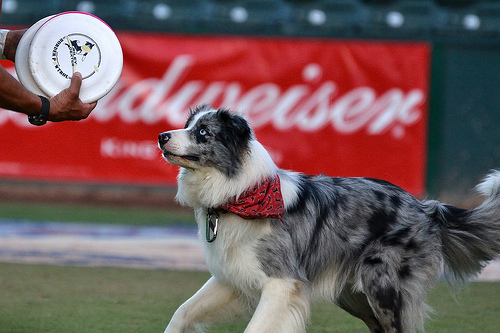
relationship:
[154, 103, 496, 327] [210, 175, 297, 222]
dog with scarf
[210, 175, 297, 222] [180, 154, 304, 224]
scarf around neck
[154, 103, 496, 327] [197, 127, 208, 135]
dog with eye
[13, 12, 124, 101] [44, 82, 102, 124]
frisbie in hand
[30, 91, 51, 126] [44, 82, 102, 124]
watch on hand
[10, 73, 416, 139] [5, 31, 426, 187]
budweiser on front of sign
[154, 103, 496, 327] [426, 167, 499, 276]
dog has tail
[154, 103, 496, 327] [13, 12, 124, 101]
dog waiting on frisbie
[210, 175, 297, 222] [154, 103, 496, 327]
scarf on neck of dog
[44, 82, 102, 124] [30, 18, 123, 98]
hand holding frisbee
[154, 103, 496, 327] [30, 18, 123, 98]
dog staring at frisbee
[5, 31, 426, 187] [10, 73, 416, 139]
sign with budweiser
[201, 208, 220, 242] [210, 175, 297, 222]
lock on scarf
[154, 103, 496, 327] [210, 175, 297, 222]
dog wearing scarf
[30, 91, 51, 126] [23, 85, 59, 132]
watch on wrist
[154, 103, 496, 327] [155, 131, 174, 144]
dog has nose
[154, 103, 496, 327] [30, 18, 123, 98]
dog looking at frisbee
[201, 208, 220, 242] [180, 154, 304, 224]
hook hanging on neck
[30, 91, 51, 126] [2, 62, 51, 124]
watch sitting on arm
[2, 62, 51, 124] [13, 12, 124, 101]
arm holding frisbees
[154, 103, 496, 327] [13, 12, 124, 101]
dog looking at frisbees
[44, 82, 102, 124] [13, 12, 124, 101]
hand holding frisbees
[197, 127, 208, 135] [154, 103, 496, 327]
eye of dog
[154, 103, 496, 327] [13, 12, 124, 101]
dog staring at frisbees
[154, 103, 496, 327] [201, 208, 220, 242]
dog wearing lock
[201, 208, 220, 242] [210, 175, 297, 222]
lock with scarf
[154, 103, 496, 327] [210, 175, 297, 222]
dog in scarf